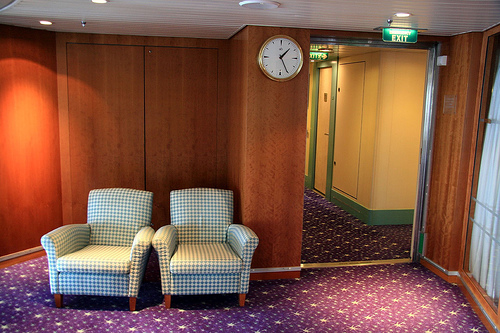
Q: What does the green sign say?
A: EXIT.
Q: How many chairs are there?
A: Two.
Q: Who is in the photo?
A: Nobody.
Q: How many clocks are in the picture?
A: One.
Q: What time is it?
A: 1:25.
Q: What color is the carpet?
A: Purple.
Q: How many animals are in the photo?
A: Zero.